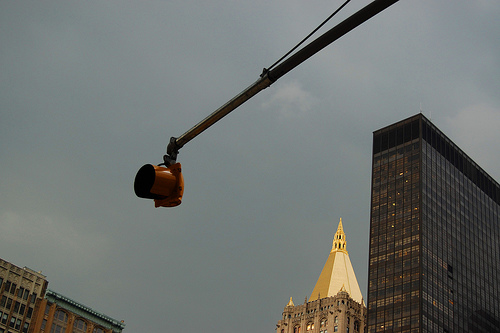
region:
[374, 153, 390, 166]
window of a building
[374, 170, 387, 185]
window of a building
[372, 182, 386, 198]
window of a building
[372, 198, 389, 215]
window of a building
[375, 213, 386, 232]
window of a building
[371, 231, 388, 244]
window of a building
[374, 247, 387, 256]
window of a building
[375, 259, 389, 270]
window of a building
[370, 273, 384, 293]
window of a building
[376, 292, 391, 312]
window of a building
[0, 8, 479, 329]
A city scene featuring the tops of buildings and a traffic signal light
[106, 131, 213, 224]
Deep orange casing of a traffic signal light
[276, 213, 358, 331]
Golden pyramid atop sky scraper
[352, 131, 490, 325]
Large thin building with many windows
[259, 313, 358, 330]
Arched windows with sun hitting them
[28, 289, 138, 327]
Green top of apartment building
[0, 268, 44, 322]
Office building with arch details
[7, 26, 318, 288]
Dark and cloudy sky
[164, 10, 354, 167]
Metal arm of traffic signal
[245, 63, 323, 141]
Small light gray cloud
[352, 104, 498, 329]
windows on the building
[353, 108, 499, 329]
tall black building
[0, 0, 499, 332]
gray clouds in the sky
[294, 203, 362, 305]
top of the building is golden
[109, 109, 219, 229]
light on the end of the pole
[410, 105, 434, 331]
corner of the building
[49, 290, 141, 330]
roof of the building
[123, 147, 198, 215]
cone around the light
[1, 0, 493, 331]
sky is light gray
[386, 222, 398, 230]
small speck on the building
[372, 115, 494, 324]
a tall building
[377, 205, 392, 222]
a window on the building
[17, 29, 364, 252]
the clouds above the buildings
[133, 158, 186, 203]
a yellow street light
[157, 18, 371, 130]
a pole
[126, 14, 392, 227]
a pole holding the street light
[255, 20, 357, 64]
a cord on the pole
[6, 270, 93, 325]
the top of buildings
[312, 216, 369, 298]
the roof of a building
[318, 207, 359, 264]
a point on the roof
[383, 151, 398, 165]
window of a building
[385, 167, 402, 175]
window of a building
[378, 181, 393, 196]
window of a building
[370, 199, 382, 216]
window of a building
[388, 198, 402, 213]
window of a building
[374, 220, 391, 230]
window of a building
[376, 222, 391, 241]
window of a building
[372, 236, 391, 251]
window of a building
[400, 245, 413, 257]
window of a building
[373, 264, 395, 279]
window of a building